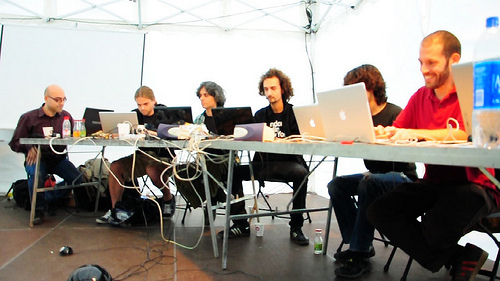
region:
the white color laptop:
[312, 82, 412, 148]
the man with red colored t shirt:
[396, 26, 466, 134]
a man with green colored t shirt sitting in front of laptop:
[341, 58, 398, 129]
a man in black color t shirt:
[251, 67, 303, 157]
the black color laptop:
[210, 98, 267, 137]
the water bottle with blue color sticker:
[466, 14, 496, 142]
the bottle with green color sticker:
[307, 224, 326, 257]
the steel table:
[208, 136, 473, 275]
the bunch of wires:
[134, 132, 221, 257]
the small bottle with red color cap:
[61, 114, 75, 140]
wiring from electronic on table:
[137, 123, 221, 258]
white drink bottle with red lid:
[60, 111, 80, 145]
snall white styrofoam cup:
[39, 120, 59, 155]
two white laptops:
[287, 84, 379, 168]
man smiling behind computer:
[407, 23, 474, 118]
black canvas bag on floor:
[7, 171, 51, 221]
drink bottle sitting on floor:
[307, 221, 337, 270]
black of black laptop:
[210, 103, 272, 153]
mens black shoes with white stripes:
[214, 214, 258, 249]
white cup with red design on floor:
[250, 212, 280, 253]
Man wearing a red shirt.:
[382, 0, 496, 273]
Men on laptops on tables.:
[23, 53, 493, 279]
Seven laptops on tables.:
[18, 86, 497, 157]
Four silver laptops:
[73, 79, 496, 151]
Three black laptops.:
[67, 101, 265, 143]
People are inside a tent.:
[4, 0, 494, 261]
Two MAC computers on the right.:
[272, 84, 387, 153]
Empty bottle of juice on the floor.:
[306, 222, 329, 260]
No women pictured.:
[3, 0, 498, 274]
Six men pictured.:
[27, 58, 494, 272]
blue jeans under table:
[320, 168, 390, 244]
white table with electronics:
[180, 123, 481, 181]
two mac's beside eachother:
[260, 88, 424, 154]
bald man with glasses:
[30, 78, 76, 123]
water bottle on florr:
[303, 223, 335, 244]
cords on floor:
[100, 210, 213, 278]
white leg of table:
[196, 166, 251, 278]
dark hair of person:
[192, 73, 249, 154]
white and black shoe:
[88, 189, 128, 220]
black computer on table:
[78, 110, 106, 155]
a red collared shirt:
[381, 72, 493, 175]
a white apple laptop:
[304, 70, 393, 155]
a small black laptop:
[190, 84, 282, 155]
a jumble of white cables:
[102, 136, 247, 248]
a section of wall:
[46, 44, 94, 79]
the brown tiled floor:
[33, 243, 55, 273]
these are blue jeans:
[311, 163, 426, 271]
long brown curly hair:
[255, 48, 308, 113]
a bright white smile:
[411, 59, 445, 90]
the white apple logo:
[331, 107, 350, 121]